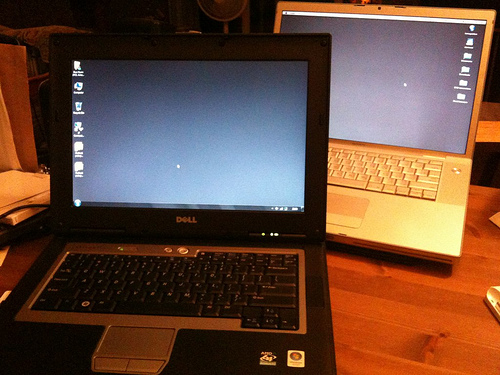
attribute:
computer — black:
[12, 41, 340, 371]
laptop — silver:
[276, 5, 496, 264]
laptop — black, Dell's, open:
[4, 25, 333, 373]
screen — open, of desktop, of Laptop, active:
[66, 53, 309, 213]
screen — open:
[281, 10, 486, 152]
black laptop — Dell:
[3, 29, 346, 371]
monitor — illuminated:
[64, 55, 311, 215]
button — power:
[177, 246, 189, 256]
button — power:
[450, 166, 461, 175]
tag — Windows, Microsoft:
[289, 345, 305, 372]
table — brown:
[2, 182, 495, 363]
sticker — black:
[255, 347, 277, 372]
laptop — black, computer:
[34, 30, 382, 370]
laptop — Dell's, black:
[38, 66, 336, 350]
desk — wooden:
[10, 172, 498, 372]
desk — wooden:
[364, 282, 437, 339]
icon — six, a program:
[69, 56, 84, 75]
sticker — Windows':
[286, 343, 304, 369]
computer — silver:
[273, 5, 493, 266]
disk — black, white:
[5, 182, 46, 229]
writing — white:
[261, 353, 271, 363]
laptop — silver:
[351, 7, 476, 265]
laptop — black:
[35, 27, 340, 372]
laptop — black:
[20, 13, 368, 340]